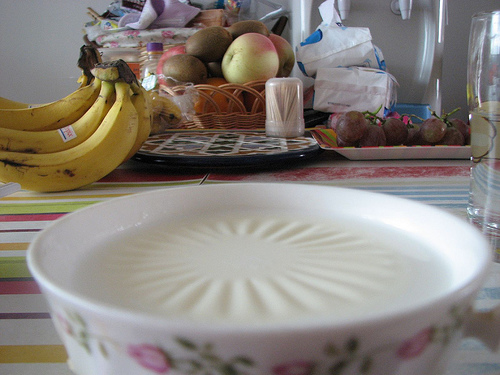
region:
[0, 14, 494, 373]
an area in a kitchen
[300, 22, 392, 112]
bags stacked on another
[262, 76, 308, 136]
a container with toothpicks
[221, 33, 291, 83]
2 apples sitting in a basket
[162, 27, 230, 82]
ripe kiwi fruits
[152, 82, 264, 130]
a fruit basket holding fruits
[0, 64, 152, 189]
a bunch of yellow bananas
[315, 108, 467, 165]
a colorful plate with fruits on top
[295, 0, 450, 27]
water dispenser knobs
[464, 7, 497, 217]
a drinking glass with design on it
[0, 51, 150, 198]
bundle of bananas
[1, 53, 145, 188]
group of yellow bananas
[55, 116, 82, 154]
small white sticker on banana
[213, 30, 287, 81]
green and red apple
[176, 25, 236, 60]
brown fuzzy kiwi in a basket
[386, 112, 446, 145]
brown fruit in a trey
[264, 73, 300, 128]
small case filled with toothpicks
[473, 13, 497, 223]
piece of a glass sitting on table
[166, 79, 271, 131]
brown basket holding fruit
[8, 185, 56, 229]
multi colored table cloth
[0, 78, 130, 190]
a ripe yellow banana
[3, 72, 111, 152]
a ripe yellow banana with sticker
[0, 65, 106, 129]
a ripe yellow banana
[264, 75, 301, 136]
a clear plastic toothpick container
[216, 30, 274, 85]
a green and red apple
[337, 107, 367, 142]
a small red grape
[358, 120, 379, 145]
a small red grape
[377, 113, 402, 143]
a small red grape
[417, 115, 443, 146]
a small red grape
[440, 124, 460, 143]
a small red grape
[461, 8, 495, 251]
clear glass half filled with water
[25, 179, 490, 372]
white bowl with pink flowers and green leaves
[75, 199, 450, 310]
whipped cream in a white bowl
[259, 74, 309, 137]
wooden toothpicks in a clear plastic holder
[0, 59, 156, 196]
bunch of yellow bananas with a sticker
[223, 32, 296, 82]
two red and green apples in a basket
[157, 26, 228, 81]
two green kiwis in a brown basket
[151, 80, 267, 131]
brown basket holding various types of fruit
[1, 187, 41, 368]
white, yellow, red and blue tablecloth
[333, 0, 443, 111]
semi clear plastic liquid dispenser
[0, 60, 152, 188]
a bunch of bananas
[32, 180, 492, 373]
a white floral dish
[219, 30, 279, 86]
a light colored apple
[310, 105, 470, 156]
grapes on a plate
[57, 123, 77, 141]
a sticker on banana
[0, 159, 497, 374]
a striped pattern table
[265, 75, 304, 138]
a plastic toothpick holder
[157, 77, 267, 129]
a brown woven basket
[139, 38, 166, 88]
the top of a bottle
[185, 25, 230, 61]
a kiwi in a basket